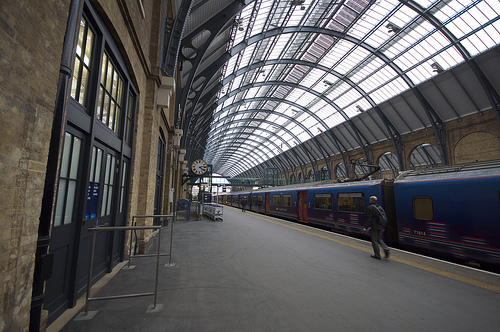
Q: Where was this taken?
A: In a train station.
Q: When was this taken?
A: During the day.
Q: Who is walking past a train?
A: The man with the backpack.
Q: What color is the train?
A: Blue.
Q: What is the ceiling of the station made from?
A: Glass.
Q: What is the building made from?
A: Brick.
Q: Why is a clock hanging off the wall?
A: To inform passengers of the time.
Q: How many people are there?
A: Two.